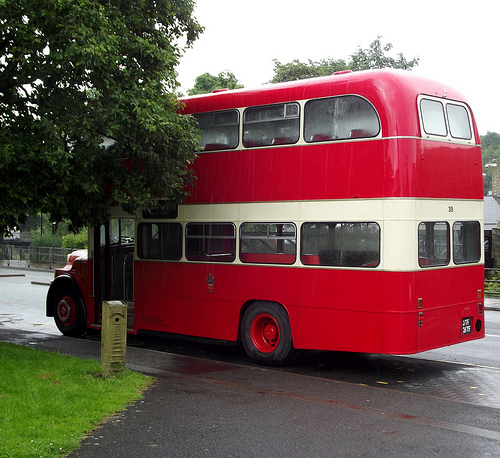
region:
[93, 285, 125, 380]
post in the grass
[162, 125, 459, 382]
the bus is parked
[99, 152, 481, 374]
the bus is red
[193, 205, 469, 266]
white band on the bus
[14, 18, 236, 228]
tree by the bus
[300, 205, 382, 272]
this is a window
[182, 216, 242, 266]
this is a window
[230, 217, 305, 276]
this is a window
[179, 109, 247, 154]
this is a window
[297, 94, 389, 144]
this is a window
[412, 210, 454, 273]
this is a window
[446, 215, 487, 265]
this is a window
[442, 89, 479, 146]
this is a window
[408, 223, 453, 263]
window on a bus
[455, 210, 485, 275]
window on a bus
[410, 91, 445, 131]
window on a bus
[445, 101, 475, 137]
window on a bus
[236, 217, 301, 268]
window on a bus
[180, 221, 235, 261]
window on a bus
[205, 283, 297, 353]
tire on a bus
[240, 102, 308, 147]
window on a bus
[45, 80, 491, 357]
red and white double decker bus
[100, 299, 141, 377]
wooden post in yard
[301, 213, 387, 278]
window in side of bus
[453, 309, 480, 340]
black license plate back of bus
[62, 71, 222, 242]
tree obscuring bus front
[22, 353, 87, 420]
green grass with a slight sheen from wetness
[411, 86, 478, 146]
back window of bus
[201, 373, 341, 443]
pavement slightly wet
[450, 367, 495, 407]
brick inlaid in street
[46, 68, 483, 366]
red and white double decker bus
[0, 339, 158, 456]
bright green patch of grass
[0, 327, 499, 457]
dark grey sidewalk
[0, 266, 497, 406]
dark grey asphalt roadway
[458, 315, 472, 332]
black and white license plate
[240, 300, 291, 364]
black tire with a red hubcap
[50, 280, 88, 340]
black tire with a red hubcap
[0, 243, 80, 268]
section of chain link fencing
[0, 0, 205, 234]
top of a tree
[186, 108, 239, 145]
glass window on bus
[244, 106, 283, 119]
glass window on bus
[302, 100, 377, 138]
glass window on bus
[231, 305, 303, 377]
the back wheel of a bus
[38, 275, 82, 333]
the front wheel of a bus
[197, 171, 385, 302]
the window of a bus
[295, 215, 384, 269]
A window on a vehicle.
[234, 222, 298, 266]
A window on a vehicle.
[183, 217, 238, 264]
A window on a vehicle.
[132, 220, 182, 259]
A window on a vehicle.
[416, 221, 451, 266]
A window on a vehicle.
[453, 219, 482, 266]
A window on a vehicle.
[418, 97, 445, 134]
A window on a vehicle.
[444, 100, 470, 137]
A window on a vehicle.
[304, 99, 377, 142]
A window on a vehicle.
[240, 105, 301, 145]
A window on a vehicle.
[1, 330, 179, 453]
The grassy area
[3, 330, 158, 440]
A grassy area near the bus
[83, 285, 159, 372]
The metal pole in the grass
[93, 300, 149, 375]
A metal pole in the grass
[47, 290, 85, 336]
The front wheel of the bus